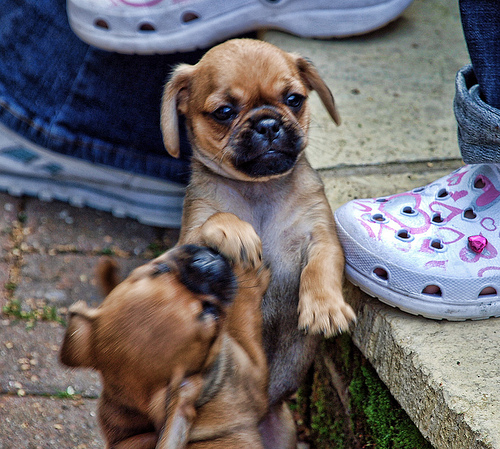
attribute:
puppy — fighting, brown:
[61, 243, 271, 448]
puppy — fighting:
[159, 38, 358, 449]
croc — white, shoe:
[334, 164, 499, 321]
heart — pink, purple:
[378, 192, 431, 233]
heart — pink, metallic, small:
[468, 234, 487, 252]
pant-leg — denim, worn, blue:
[453, 1, 499, 166]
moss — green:
[335, 337, 430, 448]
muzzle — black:
[234, 121, 298, 176]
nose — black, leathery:
[258, 119, 278, 136]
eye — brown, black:
[286, 94, 303, 108]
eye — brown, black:
[213, 106, 233, 118]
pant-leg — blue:
[0, 1, 207, 183]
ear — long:
[159, 63, 191, 157]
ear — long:
[295, 53, 341, 126]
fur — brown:
[59, 258, 272, 449]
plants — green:
[5, 298, 61, 326]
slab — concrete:
[326, 168, 499, 448]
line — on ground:
[1, 389, 98, 400]